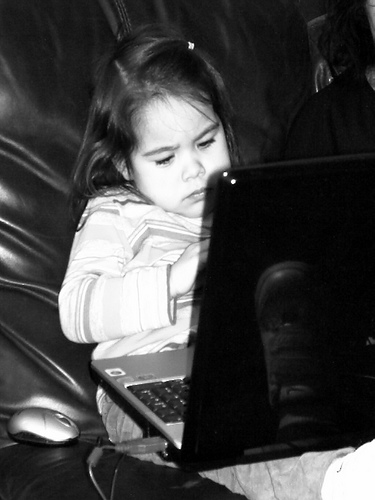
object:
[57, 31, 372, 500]
girl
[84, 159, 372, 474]
computer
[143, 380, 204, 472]
lap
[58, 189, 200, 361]
shirt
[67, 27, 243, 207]
hair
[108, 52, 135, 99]
part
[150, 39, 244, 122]
ponytail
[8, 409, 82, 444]
mouse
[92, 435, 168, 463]
plug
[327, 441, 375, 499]
shoe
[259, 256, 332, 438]
reflection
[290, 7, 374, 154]
person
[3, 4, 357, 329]
couch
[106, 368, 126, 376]
logo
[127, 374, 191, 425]
keyboard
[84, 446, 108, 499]
usb cord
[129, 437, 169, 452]
laptop port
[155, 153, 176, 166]
girl's eye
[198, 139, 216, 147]
girl's eye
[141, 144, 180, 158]
eyebrow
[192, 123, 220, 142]
eyebrow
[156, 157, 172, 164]
eyelashes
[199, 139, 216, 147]
eyelashes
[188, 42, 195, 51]
band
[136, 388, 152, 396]
key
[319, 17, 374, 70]
hair